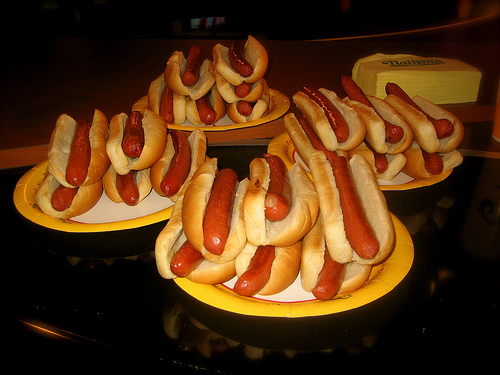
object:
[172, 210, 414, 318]
plate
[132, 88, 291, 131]
plate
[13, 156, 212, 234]
plate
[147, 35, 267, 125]
hot dogs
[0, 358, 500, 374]
ground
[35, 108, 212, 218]
hot dog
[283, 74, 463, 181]
hot dog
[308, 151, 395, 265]
bun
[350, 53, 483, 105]
butter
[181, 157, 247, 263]
bun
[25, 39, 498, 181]
wood surface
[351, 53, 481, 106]
many bananas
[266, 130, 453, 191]
paper plate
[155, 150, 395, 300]
hot dog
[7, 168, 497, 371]
table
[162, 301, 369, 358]
reflection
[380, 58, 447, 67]
logo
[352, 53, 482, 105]
napkin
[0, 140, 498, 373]
surface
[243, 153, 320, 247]
bun